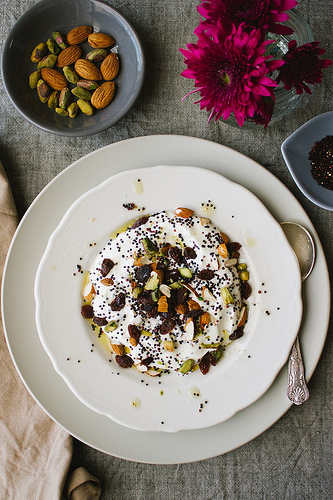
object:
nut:
[100, 53, 119, 81]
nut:
[91, 82, 116, 110]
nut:
[87, 33, 114, 48]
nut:
[41, 67, 67, 91]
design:
[288, 344, 305, 402]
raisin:
[111, 291, 127, 310]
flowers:
[179, 17, 285, 127]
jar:
[208, 7, 314, 131]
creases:
[143, 2, 205, 140]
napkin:
[0, 167, 99, 499]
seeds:
[205, 400, 208, 404]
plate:
[1, 135, 330, 465]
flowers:
[196, 0, 298, 42]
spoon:
[278, 221, 316, 405]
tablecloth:
[0, 2, 333, 499]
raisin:
[101, 258, 115, 277]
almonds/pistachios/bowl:
[1, 0, 145, 138]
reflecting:
[120, 23, 144, 104]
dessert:
[81, 207, 252, 378]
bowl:
[35, 165, 304, 432]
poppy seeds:
[308, 134, 333, 189]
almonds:
[75, 58, 103, 80]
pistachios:
[86, 45, 107, 62]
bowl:
[280, 111, 333, 211]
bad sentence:
[96, 128, 137, 140]